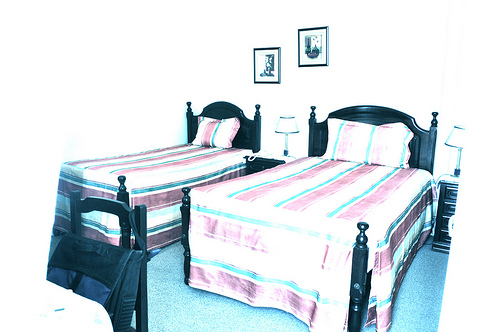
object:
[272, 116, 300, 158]
lamp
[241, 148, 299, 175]
stand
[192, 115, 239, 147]
pillow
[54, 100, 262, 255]
bed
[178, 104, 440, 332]
bed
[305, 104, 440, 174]
head board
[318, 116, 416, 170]
pillow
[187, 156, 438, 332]
bedpsread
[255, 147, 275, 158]
phone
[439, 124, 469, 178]
lamp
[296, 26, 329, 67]
picture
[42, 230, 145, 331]
bag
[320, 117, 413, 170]
pillow cover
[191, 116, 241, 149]
pillow cover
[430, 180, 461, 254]
black nightstand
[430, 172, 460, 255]
stand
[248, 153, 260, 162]
cord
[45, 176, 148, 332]
chair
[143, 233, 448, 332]
brown carpet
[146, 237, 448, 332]
floor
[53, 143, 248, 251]
bedspread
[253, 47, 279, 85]
picture